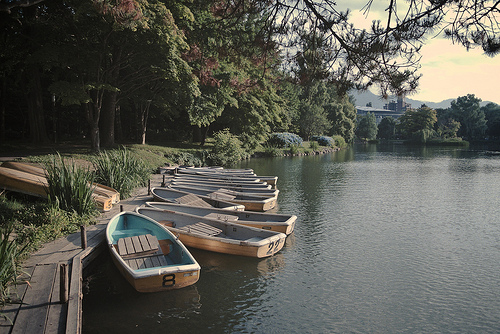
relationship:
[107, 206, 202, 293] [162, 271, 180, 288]
boat has part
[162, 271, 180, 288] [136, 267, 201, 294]
part on back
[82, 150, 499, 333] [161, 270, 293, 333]
water has ripples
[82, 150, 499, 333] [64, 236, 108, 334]
lake has edge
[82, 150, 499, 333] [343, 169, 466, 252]
water has part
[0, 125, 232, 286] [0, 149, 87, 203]
terrain has part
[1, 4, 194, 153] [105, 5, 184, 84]
tree has leaves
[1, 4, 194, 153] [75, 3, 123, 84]
tree has leaves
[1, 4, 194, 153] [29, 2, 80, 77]
tree has leaves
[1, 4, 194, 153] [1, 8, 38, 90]
tree has leaves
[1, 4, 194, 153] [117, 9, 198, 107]
tree has leaves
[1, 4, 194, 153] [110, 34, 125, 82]
tree has branch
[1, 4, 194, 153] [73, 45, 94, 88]
tree has branch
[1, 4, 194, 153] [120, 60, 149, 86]
tree has branch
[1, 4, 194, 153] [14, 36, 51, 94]
tree has branch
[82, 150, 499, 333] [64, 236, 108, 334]
water has edge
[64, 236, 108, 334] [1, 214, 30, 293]
edge has plantations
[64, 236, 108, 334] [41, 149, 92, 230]
edge has plantations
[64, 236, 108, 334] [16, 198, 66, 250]
edge has plantations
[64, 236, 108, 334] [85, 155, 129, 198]
edge has plantations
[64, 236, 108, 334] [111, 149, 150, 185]
edge has plantations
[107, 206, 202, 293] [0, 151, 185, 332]
boat in dork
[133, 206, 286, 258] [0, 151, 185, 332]
boat in dork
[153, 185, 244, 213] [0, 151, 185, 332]
boat in dork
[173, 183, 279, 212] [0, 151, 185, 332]
boat in dork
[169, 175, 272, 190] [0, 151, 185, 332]
boat in dork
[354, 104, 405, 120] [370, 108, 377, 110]
house has a section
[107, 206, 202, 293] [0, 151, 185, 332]
boat at dork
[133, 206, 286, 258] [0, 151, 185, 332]
boat at dork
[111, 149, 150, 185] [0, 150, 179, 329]
plantations next to dock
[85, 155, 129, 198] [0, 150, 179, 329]
plantations next to dock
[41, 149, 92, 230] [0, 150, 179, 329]
plantations next to dock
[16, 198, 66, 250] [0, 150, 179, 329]
plantations next to dock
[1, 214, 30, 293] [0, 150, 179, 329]
plantations next to dock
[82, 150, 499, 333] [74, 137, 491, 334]
water in river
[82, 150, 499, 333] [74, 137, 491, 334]
water at river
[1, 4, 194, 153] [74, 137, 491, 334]
tree near river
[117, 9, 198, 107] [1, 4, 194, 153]
leaves are on tree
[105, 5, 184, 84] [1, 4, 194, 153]
leaves are on tree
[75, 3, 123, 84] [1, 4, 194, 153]
leaves are on tree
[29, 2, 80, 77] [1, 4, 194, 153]
leaves are on tree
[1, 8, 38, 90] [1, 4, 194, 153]
leaves are on tree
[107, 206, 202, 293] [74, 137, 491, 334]
boat on river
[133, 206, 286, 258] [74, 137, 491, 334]
boat on river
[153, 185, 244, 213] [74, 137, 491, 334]
boat on river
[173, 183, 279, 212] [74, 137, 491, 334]
boat on river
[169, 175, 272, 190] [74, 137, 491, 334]
boat on river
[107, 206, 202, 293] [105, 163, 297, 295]
boat in row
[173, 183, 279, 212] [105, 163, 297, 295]
boat in row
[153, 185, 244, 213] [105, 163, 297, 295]
boat in row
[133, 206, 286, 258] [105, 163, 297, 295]
boat in row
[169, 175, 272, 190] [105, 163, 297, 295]
boat in row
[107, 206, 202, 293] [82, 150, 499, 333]
boat in water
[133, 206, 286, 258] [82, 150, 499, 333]
boat in water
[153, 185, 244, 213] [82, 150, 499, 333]
boat in water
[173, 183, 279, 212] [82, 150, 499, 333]
boat in water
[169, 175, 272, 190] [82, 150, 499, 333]
boat in water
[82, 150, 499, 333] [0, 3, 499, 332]
water during day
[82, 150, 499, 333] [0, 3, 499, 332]
water durig day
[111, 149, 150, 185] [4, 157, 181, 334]
plantations are at edge